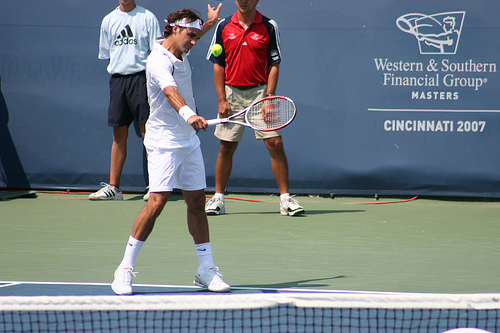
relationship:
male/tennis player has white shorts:
[110, 2, 231, 297] [141, 140, 211, 193]